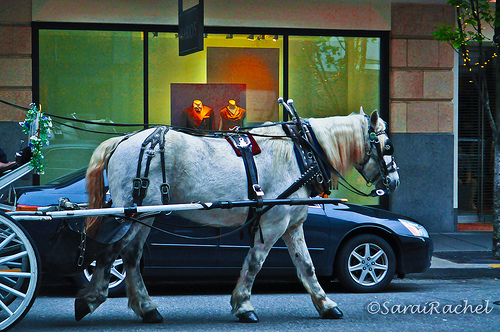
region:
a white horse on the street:
[80, 76, 397, 313]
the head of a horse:
[347, 103, 403, 198]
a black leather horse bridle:
[363, 147, 399, 183]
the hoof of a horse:
[312, 293, 347, 321]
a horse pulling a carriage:
[0, 81, 430, 311]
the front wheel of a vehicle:
[343, 235, 393, 290]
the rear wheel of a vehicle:
[81, 242, 130, 286]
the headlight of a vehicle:
[401, 218, 430, 240]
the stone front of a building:
[395, 37, 451, 128]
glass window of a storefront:
[51, 29, 377, 137]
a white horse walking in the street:
[69, 92, 406, 330]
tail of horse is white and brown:
[80, 132, 120, 256]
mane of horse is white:
[309, 103, 371, 185]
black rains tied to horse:
[6, 93, 293, 137]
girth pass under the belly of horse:
[222, 133, 267, 242]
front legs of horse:
[226, 216, 348, 328]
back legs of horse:
[71, 222, 168, 327]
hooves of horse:
[236, 300, 347, 322]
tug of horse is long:
[24, 196, 342, 226]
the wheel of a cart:
[1, 208, 43, 330]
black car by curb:
[11, 161, 435, 293]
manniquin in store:
[183, 98, 214, 130]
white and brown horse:
[79, 108, 399, 318]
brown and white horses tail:
[72, 134, 127, 237]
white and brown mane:
[310, 113, 367, 178]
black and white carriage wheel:
[0, 216, 40, 330]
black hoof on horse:
[238, 310, 258, 323]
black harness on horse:
[278, 95, 331, 196]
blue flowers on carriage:
[17, 104, 52, 179]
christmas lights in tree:
[449, 4, 499, 81]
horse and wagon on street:
[7, 15, 494, 325]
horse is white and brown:
[46, 80, 431, 322]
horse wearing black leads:
[4, 88, 373, 244]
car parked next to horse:
[4, 128, 459, 318]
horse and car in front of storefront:
[0, 51, 470, 329]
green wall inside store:
[30, 13, 415, 219]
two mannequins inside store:
[141, 65, 258, 144]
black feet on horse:
[47, 291, 362, 327]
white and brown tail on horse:
[55, 126, 133, 273]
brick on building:
[359, 13, 491, 308]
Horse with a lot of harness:
[68, 105, 404, 328]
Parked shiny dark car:
[6, 143, 436, 298]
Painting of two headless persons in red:
[168, 78, 249, 138]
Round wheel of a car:
[333, 226, 399, 294]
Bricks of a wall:
[385, 25, 460, 137]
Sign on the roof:
[172, 20, 211, 57]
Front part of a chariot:
[0, 100, 47, 329]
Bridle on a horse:
[359, 132, 401, 201]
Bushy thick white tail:
[78, 128, 124, 235]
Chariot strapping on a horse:
[118, 190, 351, 219]